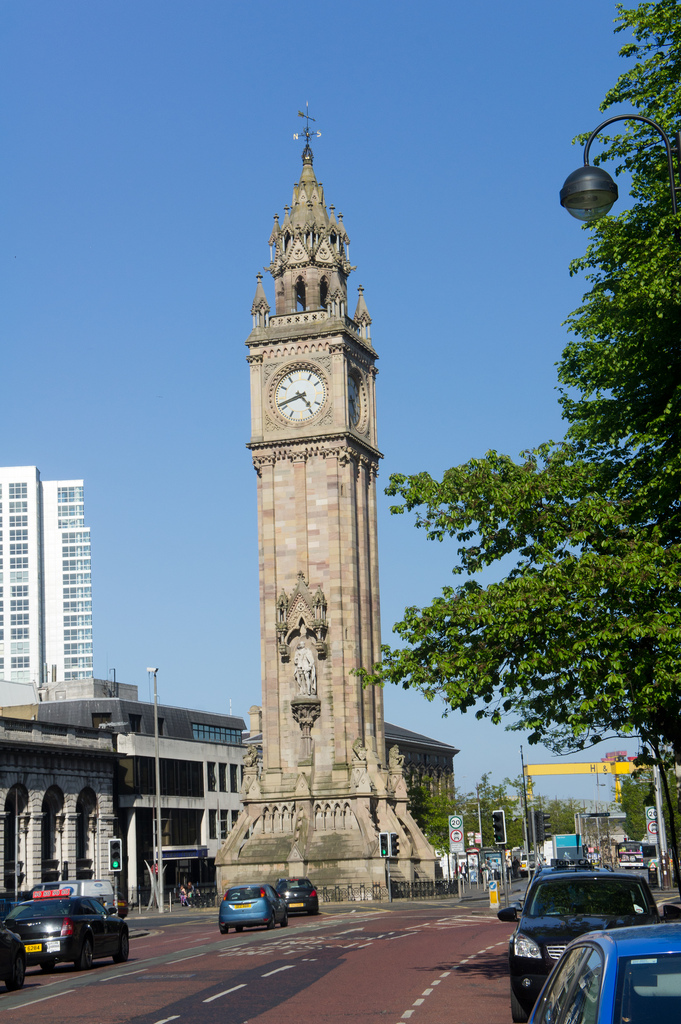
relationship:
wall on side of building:
[254, 756, 312, 790] [191, 104, 460, 912]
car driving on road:
[278, 859, 323, 917] [124, 822, 402, 1024]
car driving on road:
[225, 873, 275, 928] [112, 835, 339, 1024]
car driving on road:
[21, 885, 108, 932] [11, 863, 173, 1024]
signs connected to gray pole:
[439, 784, 493, 905] [452, 848, 469, 875]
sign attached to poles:
[495, 746, 644, 775] [569, 722, 670, 842]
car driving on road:
[517, 959, 676, 1024] [363, 810, 630, 1008]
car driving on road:
[494, 857, 680, 1023] [350, 885, 510, 1024]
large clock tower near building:
[259, 455, 396, 899] [96, 721, 317, 863]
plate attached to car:
[17, 936, 50, 963] [21, 889, 132, 973]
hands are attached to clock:
[269, 388, 314, 415] [267, 358, 335, 431]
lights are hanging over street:
[370, 830, 410, 858] [102, 874, 493, 1022]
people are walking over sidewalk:
[172, 879, 207, 907] [109, 894, 219, 922]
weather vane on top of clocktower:
[292, 99, 322, 160] [218, 112, 452, 906]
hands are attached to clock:
[279, 390, 322, 417] [270, 361, 335, 421]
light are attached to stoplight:
[106, 839, 125, 872] [109, 830, 142, 879]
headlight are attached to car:
[505, 920, 547, 965] [494, 857, 680, 1023]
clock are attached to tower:
[260, 354, 336, 425] [220, 219, 455, 892]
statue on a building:
[292, 641, 318, 694] [211, 97, 445, 912]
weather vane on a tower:
[289, 95, 322, 161] [208, 96, 455, 916]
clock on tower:
[264, 358, 334, 431] [208, 96, 455, 916]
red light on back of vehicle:
[255, 882, 271, 906] [212, 879, 291, 933]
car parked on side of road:
[494, 857, 680, 1023] [79, 854, 519, 1016]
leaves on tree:
[351, 26, 658, 750] [347, 22, 660, 887]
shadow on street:
[403, 943, 503, 990] [17, 835, 507, 1000]